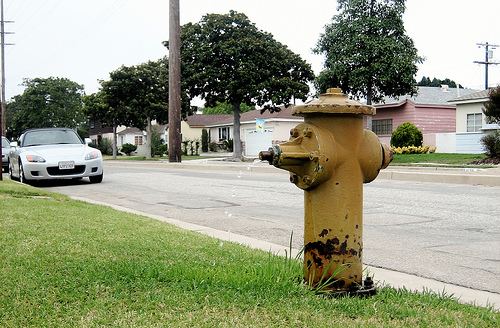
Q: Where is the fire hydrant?
A: On the side of the road.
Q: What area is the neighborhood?
A: Residential.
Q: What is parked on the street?
A: Cars.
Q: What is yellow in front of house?
A: Flowers.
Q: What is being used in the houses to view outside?
A: Windows.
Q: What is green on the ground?
A: Grass.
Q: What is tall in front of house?
A: Trees.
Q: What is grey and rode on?
A: Streets.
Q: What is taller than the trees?
A: Telegram pole.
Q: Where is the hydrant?
A: In grass.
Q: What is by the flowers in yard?
A: A bush.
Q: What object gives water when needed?
A: Hydrant.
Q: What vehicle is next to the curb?
A: Car.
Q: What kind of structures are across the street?
A: Houses.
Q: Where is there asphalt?
A: In the street.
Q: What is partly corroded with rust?
A: Bottom part of the fire hydrant.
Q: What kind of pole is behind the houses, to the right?
A: Telephone.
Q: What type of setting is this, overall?
A: Residential.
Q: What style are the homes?
A: Single-story.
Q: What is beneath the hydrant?
A: Grass.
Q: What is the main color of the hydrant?
A: Yellow.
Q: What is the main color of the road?
A: Gray.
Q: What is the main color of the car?
A: Gray.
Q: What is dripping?
A: Fire hydrant.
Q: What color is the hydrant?
A: Yellow.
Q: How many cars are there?
A: Two.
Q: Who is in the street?
A: No one.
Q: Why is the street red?
A: It isn't.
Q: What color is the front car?
A: Gray.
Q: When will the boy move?
A: No boy.